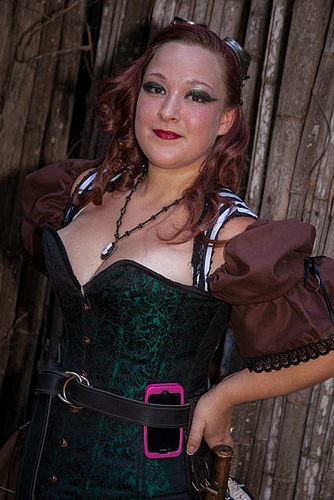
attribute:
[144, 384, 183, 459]
cell phone — smartphone, pink, an iphone, in a cover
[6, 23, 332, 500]
woman — in costume, a pirate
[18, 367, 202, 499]
belt — leather, black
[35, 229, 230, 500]
corset — dark green, green, black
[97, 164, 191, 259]
necklace — cameo, black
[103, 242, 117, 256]
figure — white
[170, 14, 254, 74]
goggles — silver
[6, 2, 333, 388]
wall — wooden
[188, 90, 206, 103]
eye — with makeup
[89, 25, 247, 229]
hair — curly, brown, red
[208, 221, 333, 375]
sleeve — red, puffy, lace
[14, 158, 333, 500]
dress — dark green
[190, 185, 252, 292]
strap — black, white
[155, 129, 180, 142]
lipstick — red